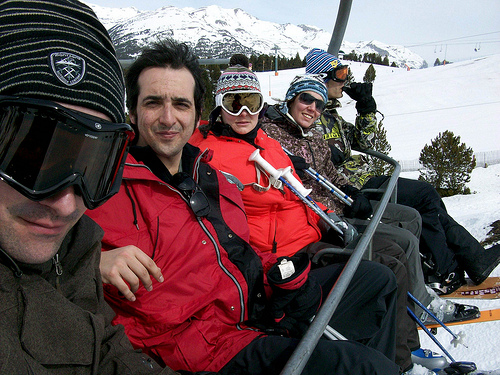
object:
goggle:
[2, 97, 136, 210]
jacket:
[104, 149, 267, 361]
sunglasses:
[298, 92, 326, 113]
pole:
[249, 148, 330, 219]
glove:
[345, 80, 378, 114]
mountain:
[174, 0, 348, 60]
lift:
[270, 44, 284, 66]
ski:
[433, 296, 482, 325]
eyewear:
[299, 93, 326, 111]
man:
[202, 53, 317, 366]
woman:
[272, 72, 335, 258]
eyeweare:
[220, 90, 265, 116]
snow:
[399, 74, 475, 130]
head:
[0, 0, 139, 268]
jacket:
[259, 110, 350, 208]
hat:
[0, 0, 122, 125]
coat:
[196, 125, 314, 288]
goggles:
[330, 65, 350, 83]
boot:
[468, 242, 499, 284]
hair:
[124, 38, 205, 103]